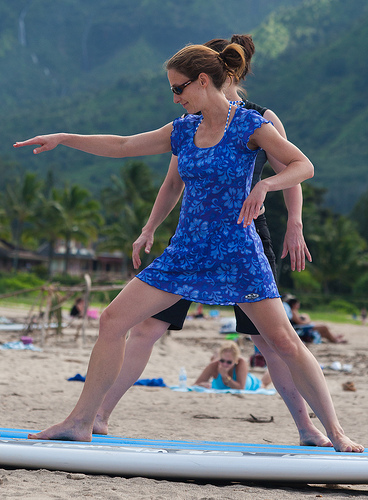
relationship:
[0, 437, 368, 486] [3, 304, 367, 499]
surfboard on sand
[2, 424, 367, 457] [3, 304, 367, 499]
surfboard on sand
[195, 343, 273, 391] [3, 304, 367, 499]
woman laying on sand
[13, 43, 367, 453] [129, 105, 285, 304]
woman wearing dress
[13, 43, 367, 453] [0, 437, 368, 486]
woman on surfboard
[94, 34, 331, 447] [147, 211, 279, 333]
woman wearing shorts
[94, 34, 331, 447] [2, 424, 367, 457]
woman on surfboard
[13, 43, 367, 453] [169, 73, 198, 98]
woman wearing glasses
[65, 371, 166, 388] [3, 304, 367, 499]
towel on sand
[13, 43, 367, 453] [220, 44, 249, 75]
woman has pony tail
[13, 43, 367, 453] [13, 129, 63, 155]
woman has hand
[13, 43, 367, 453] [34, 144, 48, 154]
woman has finger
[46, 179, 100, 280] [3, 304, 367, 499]
palm tree near sand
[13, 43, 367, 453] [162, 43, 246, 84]
woman has hair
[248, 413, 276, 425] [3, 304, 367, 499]
pipe on sand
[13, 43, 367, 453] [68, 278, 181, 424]
woman has leg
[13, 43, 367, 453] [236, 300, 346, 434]
woman has leg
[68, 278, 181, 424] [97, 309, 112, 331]
leg has knee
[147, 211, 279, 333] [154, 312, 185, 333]
shorts have edge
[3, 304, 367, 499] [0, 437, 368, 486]
sand front of surfboard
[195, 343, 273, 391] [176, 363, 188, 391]
woman near bottle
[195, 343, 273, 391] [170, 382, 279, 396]
woman lying on towel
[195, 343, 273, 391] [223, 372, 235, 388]
woman wearing watch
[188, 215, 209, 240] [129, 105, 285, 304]
flower on dress